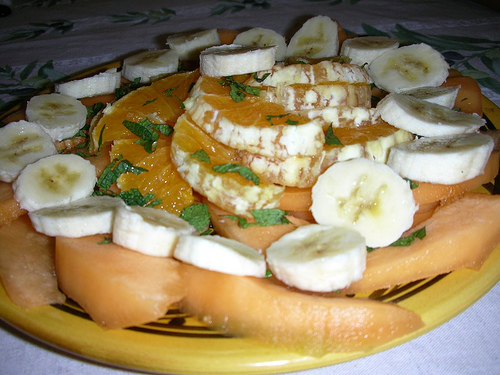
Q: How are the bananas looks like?
A: Sliced.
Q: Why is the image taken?
A: Rememberance.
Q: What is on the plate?
A: Fruits.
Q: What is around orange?
A: Banana.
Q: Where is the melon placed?
A: On bottom.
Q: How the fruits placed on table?
A: Arranged.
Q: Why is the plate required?
A: To eat.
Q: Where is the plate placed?
A: On table.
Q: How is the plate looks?
A: Circular.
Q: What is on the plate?
A: Fruit.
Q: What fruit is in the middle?
A: Oranges.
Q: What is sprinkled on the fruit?
A: Herbs.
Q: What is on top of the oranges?
A: Bananas.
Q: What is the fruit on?
A: Plate.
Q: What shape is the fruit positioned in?
A: Circle.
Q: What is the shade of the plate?
A: Yellow.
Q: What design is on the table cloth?
A: Floral.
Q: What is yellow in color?
A: The plate.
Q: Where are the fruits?
A: Arranged on plate.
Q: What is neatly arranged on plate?
A: The fruits.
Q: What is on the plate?
A: Neatly arranged fruit.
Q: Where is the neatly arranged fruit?
A: On the yellow plate.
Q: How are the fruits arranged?
A: Like a pyramid.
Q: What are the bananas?
A: Sliced.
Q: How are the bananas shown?
A: Sliced.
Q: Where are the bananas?
A: On plate sliced.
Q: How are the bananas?
A: Sliced.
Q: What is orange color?
A: Melon.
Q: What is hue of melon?
A: Orange.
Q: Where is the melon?
A: On plate.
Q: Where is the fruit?
A: On plate.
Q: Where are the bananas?
A: On plate.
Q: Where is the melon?
A: On plate.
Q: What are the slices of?
A: Orange.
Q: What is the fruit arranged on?
A: A plate.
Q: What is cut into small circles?
A: A banana.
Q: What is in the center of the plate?
A: Oranges.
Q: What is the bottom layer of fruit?
A: Melon.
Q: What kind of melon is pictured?
A: Cantaloupe.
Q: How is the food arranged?
A: In a spiral.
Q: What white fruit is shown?
A: Bananas.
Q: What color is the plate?
A: Yellow.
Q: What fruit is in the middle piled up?
A: Oranges.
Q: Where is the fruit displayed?
A: On a plate.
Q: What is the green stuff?
A: Mint leaves.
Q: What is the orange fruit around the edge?
A: Melon.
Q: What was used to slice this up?
A: Knives.